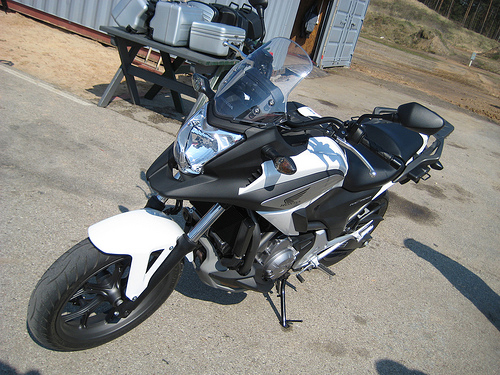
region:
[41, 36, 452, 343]
black and white motorbike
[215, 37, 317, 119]
windshield of motorbike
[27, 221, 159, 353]
front wheel of motor bike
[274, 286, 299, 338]
kick stand of motor bike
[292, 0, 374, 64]
gray shipping containers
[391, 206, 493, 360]
oil slicked asphalt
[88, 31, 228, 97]
gray wooden picnic table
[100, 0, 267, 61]
gray and black luggage on the picnic table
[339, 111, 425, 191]
seat of motorbike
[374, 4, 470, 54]
dried grass off in the back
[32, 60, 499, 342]
Motorcycle parked on cement.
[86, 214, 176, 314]
White cap on large, front wheel.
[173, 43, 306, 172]
High windshield and headlight.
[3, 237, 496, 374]
Shadows on paving.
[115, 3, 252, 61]
Silver, metal suitcases.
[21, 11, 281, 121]
Picnic table on dirt.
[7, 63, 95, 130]
Faded, white line, showing edge of paving.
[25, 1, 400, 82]
Metal structure near dirt and table.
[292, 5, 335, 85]
Open door on structure.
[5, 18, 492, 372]
Exterior shot, taken at angle.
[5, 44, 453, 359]
a black and white motor bike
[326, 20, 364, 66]
a silver container beside the door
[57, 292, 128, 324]
a black wheel cap on the bike tire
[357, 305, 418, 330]
a bike on cemented road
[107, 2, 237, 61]
suit cases on the table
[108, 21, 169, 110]
a black table beside the road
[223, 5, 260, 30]
black bag`s on the table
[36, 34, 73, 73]
brown soil on the ground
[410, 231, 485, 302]
a shadow seen on the roadside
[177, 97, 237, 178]
a silver headlight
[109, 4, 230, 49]
three metal boxes lie on a picnic table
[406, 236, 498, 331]
a black shadow dances on the gray pavement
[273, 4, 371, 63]
a gray metal door hangs open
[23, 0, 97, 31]
a metal gray storage container sits on a red support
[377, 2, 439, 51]
a large dirt mound is behind a metal storage container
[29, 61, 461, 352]
a black and white motorcycle stands on a street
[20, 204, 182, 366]
a white metal fender is attached to a thick black tire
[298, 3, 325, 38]
gray clothes are hanging inside a storage container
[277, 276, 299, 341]
a black metal kickstand supports a motorcycle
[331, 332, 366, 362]
brown oil spots soak into the pavement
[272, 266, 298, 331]
a kickstand on a motorcycle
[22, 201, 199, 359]
the front wheel of a motorcycle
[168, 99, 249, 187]
the headlight of a motorcycle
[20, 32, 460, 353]
a gray, black, and white motorcycle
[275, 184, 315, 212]
a Honda logo in black lettering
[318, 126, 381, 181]
brake lever on a motorcycle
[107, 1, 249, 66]
three silver containers on a table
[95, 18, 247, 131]
a wooden table on the ground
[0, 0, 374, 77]
a steel colored storage container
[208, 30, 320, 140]
a motorcycle's winshield